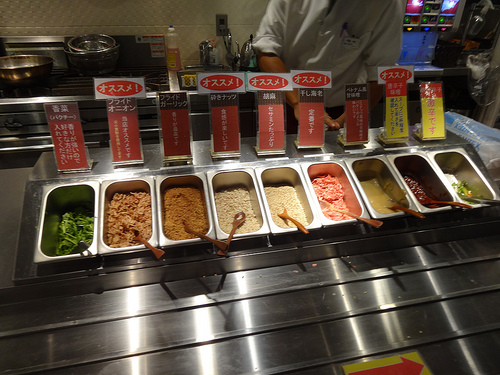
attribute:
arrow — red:
[330, 339, 439, 373]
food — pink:
[312, 172, 351, 219]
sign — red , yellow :
[415, 79, 452, 144]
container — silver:
[98, 175, 158, 257]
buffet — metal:
[29, 148, 498, 264]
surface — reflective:
[199, 303, 446, 366]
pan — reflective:
[0, 51, 56, 91]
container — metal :
[208, 160, 269, 253]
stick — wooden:
[281, 212, 306, 232]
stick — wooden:
[122, 227, 177, 261]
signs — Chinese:
[19, 65, 480, 150]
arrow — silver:
[356, 331, 418, 372]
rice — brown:
[160, 185, 209, 245]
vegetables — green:
[46, 207, 83, 254]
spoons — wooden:
[67, 187, 499, 267]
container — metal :
[298, 154, 373, 236]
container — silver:
[33, 180, 100, 270]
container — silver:
[153, 169, 215, 253]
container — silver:
[203, 160, 267, 242]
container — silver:
[254, 150, 320, 237]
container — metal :
[274, 147, 346, 209]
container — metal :
[344, 148, 414, 223]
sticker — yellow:
[339, 350, 433, 373]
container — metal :
[34, 181, 102, 261]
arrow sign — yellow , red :
[339, 348, 428, 373]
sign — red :
[42, 101, 95, 171]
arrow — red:
[342, 352, 433, 374]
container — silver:
[432, 152, 494, 208]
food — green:
[52, 187, 84, 246]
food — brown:
[104, 182, 202, 238]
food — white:
[199, 154, 291, 223]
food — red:
[403, 145, 472, 225]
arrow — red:
[351, 353, 420, 373]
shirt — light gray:
[249, 0, 407, 97]